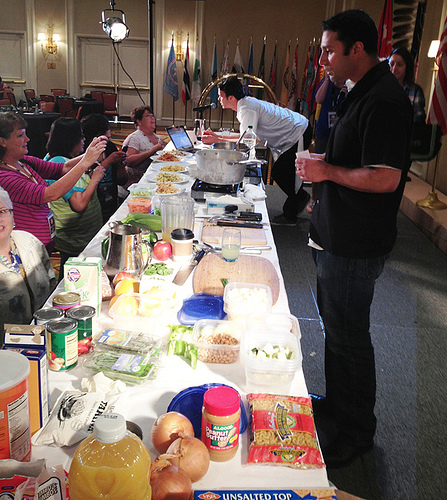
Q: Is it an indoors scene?
A: Yes, it is indoors.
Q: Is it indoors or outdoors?
A: It is indoors.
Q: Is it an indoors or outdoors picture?
A: It is indoors.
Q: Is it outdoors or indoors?
A: It is indoors.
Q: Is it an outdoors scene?
A: No, it is indoors.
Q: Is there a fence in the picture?
A: No, there are no fences.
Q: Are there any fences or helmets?
A: No, there are no fences or helmets.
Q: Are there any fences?
A: No, there are no fences.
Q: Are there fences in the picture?
A: No, there are no fences.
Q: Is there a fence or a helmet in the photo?
A: No, there are no fences or helmets.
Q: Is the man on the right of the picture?
A: Yes, the man is on the right of the image.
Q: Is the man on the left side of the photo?
A: No, the man is on the right of the image.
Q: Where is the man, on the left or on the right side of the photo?
A: The man is on the right of the image.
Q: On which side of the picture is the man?
A: The man is on the right of the image.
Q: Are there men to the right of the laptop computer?
A: Yes, there is a man to the right of the laptop computer.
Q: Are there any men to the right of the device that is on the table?
A: Yes, there is a man to the right of the laptop computer.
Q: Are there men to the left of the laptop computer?
A: No, the man is to the right of the laptop computer.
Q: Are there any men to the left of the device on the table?
A: No, the man is to the right of the laptop computer.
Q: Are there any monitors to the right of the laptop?
A: No, there is a man to the right of the laptop.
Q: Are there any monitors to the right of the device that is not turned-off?
A: No, there is a man to the right of the laptop.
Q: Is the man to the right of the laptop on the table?
A: Yes, the man is to the right of the laptop.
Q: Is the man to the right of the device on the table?
A: Yes, the man is to the right of the laptop.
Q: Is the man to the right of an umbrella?
A: No, the man is to the right of the laptop.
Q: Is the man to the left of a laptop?
A: No, the man is to the right of a laptop.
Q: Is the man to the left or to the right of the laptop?
A: The man is to the right of the laptop.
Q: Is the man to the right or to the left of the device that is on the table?
A: The man is to the right of the laptop.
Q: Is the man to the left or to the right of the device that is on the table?
A: The man is to the right of the laptop.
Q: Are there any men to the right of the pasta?
A: Yes, there is a man to the right of the pasta.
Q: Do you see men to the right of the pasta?
A: Yes, there is a man to the right of the pasta.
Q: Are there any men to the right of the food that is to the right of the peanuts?
A: Yes, there is a man to the right of the pasta.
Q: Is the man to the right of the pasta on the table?
A: Yes, the man is to the right of the pasta.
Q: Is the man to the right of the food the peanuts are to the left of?
A: Yes, the man is to the right of the pasta.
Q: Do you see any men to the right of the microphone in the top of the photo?
A: Yes, there is a man to the right of the microphone.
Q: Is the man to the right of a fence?
A: No, the man is to the right of the microphone.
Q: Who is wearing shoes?
A: The man is wearing shoes.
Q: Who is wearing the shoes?
A: The man is wearing shoes.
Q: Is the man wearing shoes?
A: Yes, the man is wearing shoes.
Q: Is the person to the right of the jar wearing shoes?
A: Yes, the man is wearing shoes.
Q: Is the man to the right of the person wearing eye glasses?
A: No, the man is wearing shoes.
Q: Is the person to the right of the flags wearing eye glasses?
A: No, the man is wearing shoes.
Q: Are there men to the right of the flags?
A: Yes, there is a man to the right of the flags.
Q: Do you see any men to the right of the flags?
A: Yes, there is a man to the right of the flags.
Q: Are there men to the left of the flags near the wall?
A: No, the man is to the right of the flags.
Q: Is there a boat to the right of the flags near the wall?
A: No, there is a man to the right of the flags.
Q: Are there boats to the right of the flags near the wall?
A: No, there is a man to the right of the flags.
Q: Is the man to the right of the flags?
A: Yes, the man is to the right of the flags.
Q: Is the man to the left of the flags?
A: No, the man is to the right of the flags.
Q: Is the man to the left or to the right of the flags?
A: The man is to the right of the flags.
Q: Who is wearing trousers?
A: The man is wearing trousers.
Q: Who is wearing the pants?
A: The man is wearing trousers.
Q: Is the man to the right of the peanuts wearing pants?
A: Yes, the man is wearing pants.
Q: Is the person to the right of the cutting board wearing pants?
A: Yes, the man is wearing pants.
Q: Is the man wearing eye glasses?
A: No, the man is wearing pants.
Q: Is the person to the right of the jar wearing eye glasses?
A: No, the man is wearing pants.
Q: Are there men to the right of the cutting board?
A: Yes, there is a man to the right of the cutting board.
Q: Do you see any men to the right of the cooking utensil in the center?
A: Yes, there is a man to the right of the cutting board.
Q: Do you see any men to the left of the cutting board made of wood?
A: No, the man is to the right of the cutting board.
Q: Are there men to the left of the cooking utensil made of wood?
A: No, the man is to the right of the cutting board.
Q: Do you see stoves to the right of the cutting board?
A: No, there is a man to the right of the cutting board.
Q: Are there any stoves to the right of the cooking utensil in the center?
A: No, there is a man to the right of the cutting board.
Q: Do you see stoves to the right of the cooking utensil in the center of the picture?
A: No, there is a man to the right of the cutting board.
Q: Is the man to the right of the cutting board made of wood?
A: Yes, the man is to the right of the cutting board.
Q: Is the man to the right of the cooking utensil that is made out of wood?
A: Yes, the man is to the right of the cutting board.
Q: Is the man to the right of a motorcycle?
A: No, the man is to the right of the cutting board.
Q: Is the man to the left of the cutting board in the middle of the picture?
A: No, the man is to the right of the cutting board.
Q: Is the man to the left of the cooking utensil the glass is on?
A: No, the man is to the right of the cutting board.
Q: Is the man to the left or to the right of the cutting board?
A: The man is to the right of the cutting board.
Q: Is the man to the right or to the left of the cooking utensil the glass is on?
A: The man is to the right of the cutting board.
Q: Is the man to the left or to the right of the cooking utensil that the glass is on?
A: The man is to the right of the cutting board.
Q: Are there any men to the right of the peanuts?
A: Yes, there is a man to the right of the peanuts.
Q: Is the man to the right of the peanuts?
A: Yes, the man is to the right of the peanuts.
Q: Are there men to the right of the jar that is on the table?
A: Yes, there is a man to the right of the jar.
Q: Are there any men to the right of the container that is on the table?
A: Yes, there is a man to the right of the jar.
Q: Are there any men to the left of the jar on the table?
A: No, the man is to the right of the jar.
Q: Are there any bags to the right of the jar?
A: No, there is a man to the right of the jar.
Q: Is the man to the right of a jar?
A: Yes, the man is to the right of a jar.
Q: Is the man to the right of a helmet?
A: No, the man is to the right of a jar.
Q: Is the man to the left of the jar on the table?
A: No, the man is to the right of the jar.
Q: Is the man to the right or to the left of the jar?
A: The man is to the right of the jar.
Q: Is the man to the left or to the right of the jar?
A: The man is to the right of the jar.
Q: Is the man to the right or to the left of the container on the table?
A: The man is to the right of the jar.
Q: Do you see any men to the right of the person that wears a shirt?
A: Yes, there is a man to the right of the person.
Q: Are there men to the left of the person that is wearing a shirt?
A: No, the man is to the right of the person.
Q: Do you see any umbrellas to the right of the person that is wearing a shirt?
A: No, there is a man to the right of the person.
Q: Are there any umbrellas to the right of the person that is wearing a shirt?
A: No, there is a man to the right of the person.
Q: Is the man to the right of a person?
A: Yes, the man is to the right of a person.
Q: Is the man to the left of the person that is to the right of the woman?
A: No, the man is to the right of the person.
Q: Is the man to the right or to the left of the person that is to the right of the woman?
A: The man is to the right of the person.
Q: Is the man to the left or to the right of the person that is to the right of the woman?
A: The man is to the right of the person.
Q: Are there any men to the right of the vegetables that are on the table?
A: Yes, there is a man to the right of the onions.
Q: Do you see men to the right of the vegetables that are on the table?
A: Yes, there is a man to the right of the onions.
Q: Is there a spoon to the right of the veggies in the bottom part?
A: No, there is a man to the right of the onions.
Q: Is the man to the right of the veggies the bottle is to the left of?
A: Yes, the man is to the right of the onions.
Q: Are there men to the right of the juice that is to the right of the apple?
A: Yes, there is a man to the right of the juice.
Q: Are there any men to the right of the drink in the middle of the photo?
A: Yes, there is a man to the right of the juice.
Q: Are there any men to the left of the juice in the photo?
A: No, the man is to the right of the juice.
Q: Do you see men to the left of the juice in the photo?
A: No, the man is to the right of the juice.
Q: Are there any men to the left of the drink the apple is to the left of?
A: No, the man is to the right of the juice.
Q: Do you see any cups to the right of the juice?
A: No, there is a man to the right of the juice.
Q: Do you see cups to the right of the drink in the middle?
A: No, there is a man to the right of the juice.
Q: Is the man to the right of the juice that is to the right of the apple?
A: Yes, the man is to the right of the juice.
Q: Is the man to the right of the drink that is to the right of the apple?
A: Yes, the man is to the right of the juice.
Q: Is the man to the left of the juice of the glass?
A: No, the man is to the right of the juice.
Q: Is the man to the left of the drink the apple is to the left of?
A: No, the man is to the right of the juice.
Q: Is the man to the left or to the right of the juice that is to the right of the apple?
A: The man is to the right of the juice.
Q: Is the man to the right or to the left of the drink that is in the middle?
A: The man is to the right of the juice.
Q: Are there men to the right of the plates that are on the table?
A: Yes, there is a man to the right of the plates.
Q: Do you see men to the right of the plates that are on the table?
A: Yes, there is a man to the right of the plates.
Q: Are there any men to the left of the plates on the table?
A: No, the man is to the right of the plates.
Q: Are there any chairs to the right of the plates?
A: No, there is a man to the right of the plates.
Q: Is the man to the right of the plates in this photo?
A: Yes, the man is to the right of the plates.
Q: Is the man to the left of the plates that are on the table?
A: No, the man is to the right of the plates.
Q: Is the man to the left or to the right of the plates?
A: The man is to the right of the plates.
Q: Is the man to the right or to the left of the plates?
A: The man is to the right of the plates.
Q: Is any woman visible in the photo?
A: Yes, there is a woman.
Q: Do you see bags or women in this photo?
A: Yes, there is a woman.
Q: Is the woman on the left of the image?
A: Yes, the woman is on the left of the image.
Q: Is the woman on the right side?
A: No, the woman is on the left of the image.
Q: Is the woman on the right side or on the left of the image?
A: The woman is on the left of the image.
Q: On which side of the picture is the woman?
A: The woman is on the left of the image.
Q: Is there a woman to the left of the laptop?
A: Yes, there is a woman to the left of the laptop.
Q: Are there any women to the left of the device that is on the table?
A: Yes, there is a woman to the left of the laptop.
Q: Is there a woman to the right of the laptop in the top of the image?
A: No, the woman is to the left of the laptop.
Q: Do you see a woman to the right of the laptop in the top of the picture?
A: No, the woman is to the left of the laptop.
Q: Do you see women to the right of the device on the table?
A: No, the woman is to the left of the laptop.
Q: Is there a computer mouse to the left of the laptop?
A: No, there is a woman to the left of the laptop.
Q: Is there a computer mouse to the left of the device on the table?
A: No, there is a woman to the left of the laptop.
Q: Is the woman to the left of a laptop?
A: Yes, the woman is to the left of a laptop.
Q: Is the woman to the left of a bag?
A: No, the woman is to the left of a laptop.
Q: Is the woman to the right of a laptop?
A: No, the woman is to the left of a laptop.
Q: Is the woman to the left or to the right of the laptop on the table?
A: The woman is to the left of the laptop computer.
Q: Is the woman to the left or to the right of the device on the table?
A: The woman is to the left of the laptop computer.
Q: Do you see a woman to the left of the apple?
A: Yes, there is a woman to the left of the apple.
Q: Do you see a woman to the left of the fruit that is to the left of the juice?
A: Yes, there is a woman to the left of the apple.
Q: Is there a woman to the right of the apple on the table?
A: No, the woman is to the left of the apple.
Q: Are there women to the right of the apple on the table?
A: No, the woman is to the left of the apple.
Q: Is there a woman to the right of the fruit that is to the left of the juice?
A: No, the woman is to the left of the apple.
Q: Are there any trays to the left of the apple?
A: No, there is a woman to the left of the apple.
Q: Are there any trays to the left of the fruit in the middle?
A: No, there is a woman to the left of the apple.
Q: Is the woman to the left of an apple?
A: Yes, the woman is to the left of an apple.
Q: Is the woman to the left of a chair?
A: No, the woman is to the left of an apple.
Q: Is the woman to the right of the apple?
A: No, the woman is to the left of the apple.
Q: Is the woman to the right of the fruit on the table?
A: No, the woman is to the left of the apple.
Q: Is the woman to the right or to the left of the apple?
A: The woman is to the left of the apple.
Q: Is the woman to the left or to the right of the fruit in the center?
A: The woman is to the left of the apple.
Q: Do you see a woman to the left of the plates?
A: Yes, there is a woman to the left of the plates.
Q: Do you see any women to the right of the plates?
A: No, the woman is to the left of the plates.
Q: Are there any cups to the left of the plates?
A: No, there is a woman to the left of the plates.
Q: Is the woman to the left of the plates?
A: Yes, the woman is to the left of the plates.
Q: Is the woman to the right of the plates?
A: No, the woman is to the left of the plates.